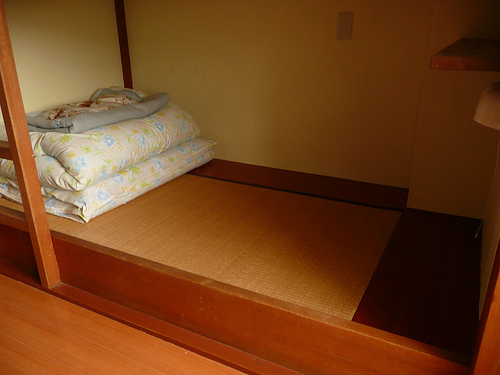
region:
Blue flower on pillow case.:
[102, 135, 120, 149]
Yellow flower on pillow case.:
[67, 143, 77, 158]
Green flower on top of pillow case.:
[136, 171, 155, 194]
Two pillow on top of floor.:
[56, 126, 190, 212]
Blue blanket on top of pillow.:
[58, 108, 114, 129]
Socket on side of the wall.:
[336, 8, 363, 55]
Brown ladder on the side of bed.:
[2, 46, 64, 295]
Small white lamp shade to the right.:
[472, 101, 495, 128]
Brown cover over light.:
[435, 30, 497, 67]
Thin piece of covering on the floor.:
[238, 183, 345, 300]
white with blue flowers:
[14, 103, 226, 222]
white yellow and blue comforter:
[22, 110, 204, 177]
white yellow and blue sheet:
[14, 141, 230, 218]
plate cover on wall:
[325, 8, 365, 48]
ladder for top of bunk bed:
[6, 10, 63, 282]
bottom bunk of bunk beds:
[9, 107, 472, 373]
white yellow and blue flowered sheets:
[16, 77, 213, 245]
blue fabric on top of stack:
[29, 82, 160, 139]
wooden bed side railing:
[0, 212, 456, 373]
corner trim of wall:
[109, 4, 144, 87]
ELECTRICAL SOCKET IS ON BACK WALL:
[334, 9, 362, 45]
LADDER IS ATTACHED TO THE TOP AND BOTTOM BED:
[2, 20, 58, 271]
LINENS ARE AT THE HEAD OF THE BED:
[0, 128, 202, 230]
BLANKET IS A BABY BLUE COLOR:
[20, 80, 155, 137]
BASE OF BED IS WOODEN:
[145, 163, 484, 348]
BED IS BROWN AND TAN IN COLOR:
[8, 114, 473, 360]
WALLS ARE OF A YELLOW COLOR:
[139, 3, 402, 183]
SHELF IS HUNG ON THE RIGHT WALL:
[430, 31, 487, 76]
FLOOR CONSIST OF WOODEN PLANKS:
[1, 283, 228, 363]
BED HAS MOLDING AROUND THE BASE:
[181, 143, 407, 213]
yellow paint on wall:
[245, 48, 358, 101]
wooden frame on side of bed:
[142, 288, 242, 330]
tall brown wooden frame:
[4, 155, 79, 301]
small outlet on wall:
[332, 7, 363, 42]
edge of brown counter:
[418, 26, 498, 80]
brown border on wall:
[108, 20, 138, 55]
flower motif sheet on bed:
[46, 170, 216, 220]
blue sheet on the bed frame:
[42, 70, 171, 135]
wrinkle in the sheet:
[61, 169, 91, 189]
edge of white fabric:
[463, 86, 495, 131]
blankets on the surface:
[15, 65, 240, 235]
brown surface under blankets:
[160, 185, 280, 245]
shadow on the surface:
[261, 206, 336, 266]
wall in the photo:
[215, 86, 342, 156]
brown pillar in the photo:
[11, 85, 61, 261]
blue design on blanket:
[96, 128, 122, 153]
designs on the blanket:
[67, 126, 157, 172]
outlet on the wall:
[320, 5, 367, 51]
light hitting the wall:
[5, 30, 75, 105]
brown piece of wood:
[110, 268, 199, 324]